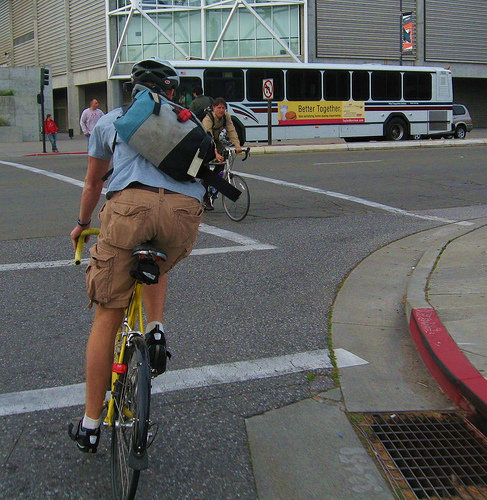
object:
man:
[61, 56, 213, 450]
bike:
[73, 217, 171, 500]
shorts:
[83, 187, 204, 309]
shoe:
[67, 417, 101, 454]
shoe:
[144, 323, 171, 379]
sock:
[81, 413, 102, 430]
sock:
[144, 321, 165, 338]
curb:
[405, 302, 487, 419]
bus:
[167, 57, 454, 144]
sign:
[277, 101, 366, 127]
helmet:
[131, 56, 180, 93]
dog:
[402, 26, 411, 43]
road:
[1, 137, 487, 499]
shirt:
[87, 106, 207, 204]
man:
[80, 97, 106, 154]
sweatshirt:
[79, 108, 104, 135]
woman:
[44, 114, 60, 153]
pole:
[37, 63, 50, 153]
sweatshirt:
[44, 119, 58, 134]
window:
[202, 67, 245, 105]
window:
[245, 68, 285, 103]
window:
[286, 69, 323, 104]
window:
[322, 68, 351, 101]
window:
[351, 69, 372, 101]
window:
[370, 68, 402, 102]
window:
[403, 71, 432, 102]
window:
[175, 75, 203, 99]